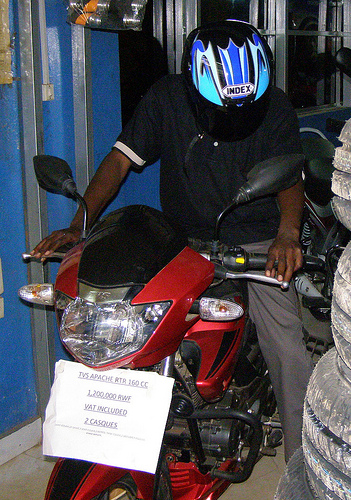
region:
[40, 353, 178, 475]
White paper with black prints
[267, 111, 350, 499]
Tall heap of tires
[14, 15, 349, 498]
Person sitting on a motorcycle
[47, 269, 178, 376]
Headlamp of a motorcycle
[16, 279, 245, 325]
Pair of indicator lamps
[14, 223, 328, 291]
Pair of hands on controls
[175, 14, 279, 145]
Black helmet with blue shades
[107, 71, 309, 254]
Black short sleeved shirt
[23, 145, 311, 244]
Pair of rear view mirrors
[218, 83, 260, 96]
Writing on the helmet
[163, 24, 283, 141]
head of a person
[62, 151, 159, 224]
arm of a person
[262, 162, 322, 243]
arm of a person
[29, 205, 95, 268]
hand of a person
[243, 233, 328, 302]
hand of a person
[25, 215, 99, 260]
a hand of a person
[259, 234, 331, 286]
a hand of a person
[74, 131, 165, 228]
an arm of a person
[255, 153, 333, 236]
an arm of a person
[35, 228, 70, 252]
finger of a person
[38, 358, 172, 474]
sign describing scooter for sale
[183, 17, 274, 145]
person wearing integral safety helmet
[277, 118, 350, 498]
tires partially seen on side of picture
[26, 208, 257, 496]
scooter is black and red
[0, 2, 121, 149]
wall behind man is blue and grey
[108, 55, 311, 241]
man wearing black polo shirt with white stripes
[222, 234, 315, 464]
man wearing grey slacks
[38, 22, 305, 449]
man sitting on scooter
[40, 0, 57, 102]
electric fixture on wall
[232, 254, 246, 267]
button on scooter is yellow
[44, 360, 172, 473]
piece of white paper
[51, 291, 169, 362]
the headlight is off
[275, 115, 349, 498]
a stack of tires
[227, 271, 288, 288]
metal handle bars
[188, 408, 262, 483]
a black foot hold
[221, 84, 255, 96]
a white logo on the helmet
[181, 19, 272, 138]
a motorcycle helmet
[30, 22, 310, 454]
the man is sitting on the motorcycle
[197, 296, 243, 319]
a blinker light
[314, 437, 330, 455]
dirt on the tread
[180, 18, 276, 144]
Blue and black motorcycle helmet.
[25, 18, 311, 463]
Man wearing a black t shirt.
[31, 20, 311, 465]
Man wearing grey pants.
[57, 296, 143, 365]
Headlight of a red motorcycle.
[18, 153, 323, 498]
Red motorcycle with someone sitting on it.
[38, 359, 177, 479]
White piece of paper with black letters on it.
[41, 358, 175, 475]
White piece of paper attached to a motorcycle.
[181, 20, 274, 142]
Motorcycle with the word index on it.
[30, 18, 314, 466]
Man with two hands.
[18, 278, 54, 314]
Turn signal on a motorcycle.